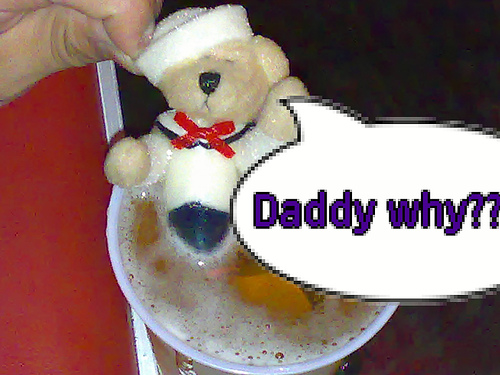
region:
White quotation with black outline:
[222, 94, 499, 301]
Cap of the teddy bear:
[116, 7, 255, 81]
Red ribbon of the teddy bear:
[171, 112, 239, 157]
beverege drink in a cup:
[105, 163, 409, 373]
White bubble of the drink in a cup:
[155, 301, 298, 365]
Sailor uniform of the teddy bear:
[138, 104, 291, 261]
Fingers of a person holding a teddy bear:
[0, 0, 172, 105]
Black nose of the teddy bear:
[195, 72, 227, 92]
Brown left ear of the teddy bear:
[253, 34, 295, 86]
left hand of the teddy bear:
[101, 131, 154, 194]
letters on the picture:
[249, 189, 493, 239]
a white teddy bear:
[121, 27, 313, 277]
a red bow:
[173, 111, 240, 160]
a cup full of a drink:
[111, 171, 399, 358]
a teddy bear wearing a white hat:
[141, 11, 285, 283]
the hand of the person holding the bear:
[1, 3, 162, 87]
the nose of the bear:
[198, 73, 219, 90]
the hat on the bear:
[142, 8, 257, 83]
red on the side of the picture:
[3, 61, 131, 372]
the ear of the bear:
[253, 34, 286, 81]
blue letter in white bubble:
[252, 192, 275, 231]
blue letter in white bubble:
[279, 196, 303, 233]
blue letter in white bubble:
[302, 188, 330, 230]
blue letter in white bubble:
[327, 187, 351, 229]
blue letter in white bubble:
[349, 194, 378, 236]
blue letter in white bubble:
[383, 199, 420, 229]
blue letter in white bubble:
[420, 189, 444, 229]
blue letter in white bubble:
[441, 198, 468, 236]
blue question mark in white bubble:
[467, 190, 482, 237]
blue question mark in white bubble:
[486, 189, 496, 230]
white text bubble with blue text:
[224, 94, 496, 317]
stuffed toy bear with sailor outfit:
[104, 25, 310, 247]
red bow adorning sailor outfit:
[168, 110, 240, 161]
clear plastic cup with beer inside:
[100, 93, 400, 368]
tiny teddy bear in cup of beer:
[101, 13, 323, 288]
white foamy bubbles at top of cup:
[156, 296, 329, 373]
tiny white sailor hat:
[133, 0, 255, 77]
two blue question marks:
[465, 183, 498, 230]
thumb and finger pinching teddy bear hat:
[0, 2, 163, 68]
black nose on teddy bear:
[196, 70, 226, 94]